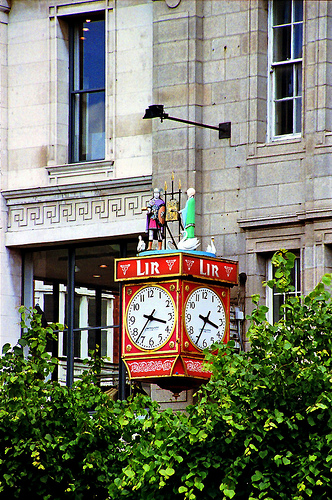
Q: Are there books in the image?
A: No, there are no books.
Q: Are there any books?
A: No, there are no books.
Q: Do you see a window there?
A: Yes, there is a window.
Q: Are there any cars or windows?
A: Yes, there is a window.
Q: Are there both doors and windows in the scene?
A: No, there is a window but no doors.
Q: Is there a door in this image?
A: No, there are no doors.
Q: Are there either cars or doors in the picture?
A: No, there are no doors or cars.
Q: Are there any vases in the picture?
A: No, there are no vases.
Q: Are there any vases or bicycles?
A: No, there are no vases or bicycles.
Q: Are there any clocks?
A: Yes, there is a clock.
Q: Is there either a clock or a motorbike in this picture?
A: Yes, there is a clock.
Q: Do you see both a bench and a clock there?
A: No, there is a clock but no benches.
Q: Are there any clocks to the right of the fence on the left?
A: Yes, there is a clock to the right of the fence.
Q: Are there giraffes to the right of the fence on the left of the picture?
A: No, there is a clock to the right of the fence.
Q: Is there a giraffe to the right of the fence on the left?
A: No, there is a clock to the right of the fence.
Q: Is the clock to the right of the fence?
A: Yes, the clock is to the right of the fence.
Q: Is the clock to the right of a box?
A: No, the clock is to the right of the fence.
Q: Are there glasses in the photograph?
A: No, there are no glasses.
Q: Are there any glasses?
A: No, there are no glasses.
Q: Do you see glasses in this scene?
A: No, there are no glasses.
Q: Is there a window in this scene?
A: Yes, there is a window.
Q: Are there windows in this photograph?
A: Yes, there is a window.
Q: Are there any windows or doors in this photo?
A: Yes, there is a window.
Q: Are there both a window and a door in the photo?
A: No, there is a window but no doors.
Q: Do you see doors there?
A: No, there are no doors.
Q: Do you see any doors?
A: No, there are no doors.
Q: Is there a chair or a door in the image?
A: No, there are no doors or chairs.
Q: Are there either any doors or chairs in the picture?
A: No, there are no doors or chairs.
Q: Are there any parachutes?
A: No, there are no parachutes.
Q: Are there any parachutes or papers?
A: No, there are no parachutes or papers.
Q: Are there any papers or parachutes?
A: No, there are no parachutes or papers.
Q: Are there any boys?
A: No, there are no boys.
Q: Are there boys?
A: No, there are no boys.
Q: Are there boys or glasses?
A: No, there are no boys or glasses.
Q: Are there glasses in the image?
A: No, there are no glasses.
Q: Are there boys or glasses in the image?
A: No, there are no glasses or boys.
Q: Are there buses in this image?
A: No, there are no buses.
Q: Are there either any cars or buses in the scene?
A: No, there are no buses or cars.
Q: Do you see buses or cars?
A: No, there are no buses or cars.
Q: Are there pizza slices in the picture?
A: No, there are no pizza slices.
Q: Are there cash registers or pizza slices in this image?
A: No, there are no pizza slices or cash registers.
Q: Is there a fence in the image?
A: Yes, there is a fence.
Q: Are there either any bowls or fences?
A: Yes, there is a fence.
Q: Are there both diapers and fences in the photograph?
A: No, there is a fence but no diapers.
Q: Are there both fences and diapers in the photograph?
A: No, there is a fence but no diapers.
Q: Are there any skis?
A: No, there are no skis.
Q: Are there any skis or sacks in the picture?
A: No, there are no skis or sacks.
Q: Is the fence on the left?
A: Yes, the fence is on the left of the image.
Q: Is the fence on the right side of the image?
A: No, the fence is on the left of the image.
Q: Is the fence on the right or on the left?
A: The fence is on the left of the image.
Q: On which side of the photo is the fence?
A: The fence is on the left of the image.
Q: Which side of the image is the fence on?
A: The fence is on the left of the image.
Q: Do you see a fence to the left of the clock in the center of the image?
A: Yes, there is a fence to the left of the clock.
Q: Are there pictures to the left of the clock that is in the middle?
A: No, there is a fence to the left of the clock.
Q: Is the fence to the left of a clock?
A: Yes, the fence is to the left of a clock.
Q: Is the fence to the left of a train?
A: No, the fence is to the left of a clock.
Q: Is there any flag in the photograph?
A: No, there are no flags.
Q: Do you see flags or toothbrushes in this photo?
A: No, there are no flags or toothbrushes.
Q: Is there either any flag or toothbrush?
A: No, there are no flags or toothbrushes.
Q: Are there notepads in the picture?
A: No, there are no notepads.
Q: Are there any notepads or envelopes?
A: No, there are no notepads or envelopes.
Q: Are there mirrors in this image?
A: No, there are no mirrors.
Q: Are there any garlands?
A: No, there are no garlands.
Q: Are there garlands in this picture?
A: No, there are no garlands.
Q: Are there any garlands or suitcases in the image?
A: No, there are no garlands or suitcases.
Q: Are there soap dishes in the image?
A: No, there are no soap dishes.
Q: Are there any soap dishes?
A: No, there are no soap dishes.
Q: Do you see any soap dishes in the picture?
A: No, there are no soap dishes.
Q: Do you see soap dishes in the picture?
A: No, there are no soap dishes.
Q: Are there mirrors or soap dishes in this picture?
A: No, there are no soap dishes or mirrors.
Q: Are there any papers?
A: No, there are no papers.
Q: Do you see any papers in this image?
A: No, there are no papers.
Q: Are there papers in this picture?
A: No, there are no papers.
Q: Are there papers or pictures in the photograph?
A: No, there are no papers or pictures.